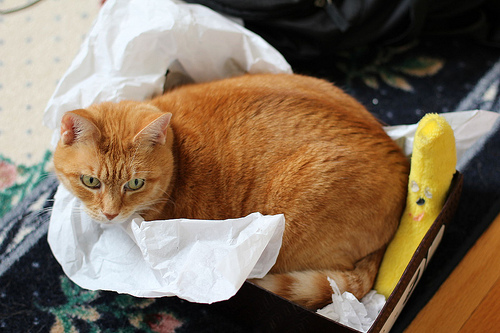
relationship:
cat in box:
[52, 70, 410, 315] [159, 68, 464, 331]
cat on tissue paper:
[52, 70, 410, 315] [47, 1, 499, 330]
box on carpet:
[159, 68, 464, 331] [2, 1, 499, 332]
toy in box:
[375, 112, 458, 302] [159, 68, 464, 331]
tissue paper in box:
[47, 1, 499, 330] [159, 68, 464, 331]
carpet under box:
[2, 1, 499, 332] [159, 68, 464, 331]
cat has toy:
[52, 70, 410, 315] [375, 112, 458, 302]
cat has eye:
[52, 70, 410, 315] [123, 174, 148, 193]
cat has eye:
[52, 70, 410, 315] [79, 172, 101, 191]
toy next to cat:
[375, 112, 458, 302] [52, 70, 410, 315]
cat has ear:
[52, 70, 410, 315] [132, 112, 174, 147]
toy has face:
[375, 112, 458, 302] [406, 181, 435, 221]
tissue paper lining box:
[47, 1, 499, 330] [159, 68, 464, 331]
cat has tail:
[52, 70, 410, 315] [249, 248, 384, 309]